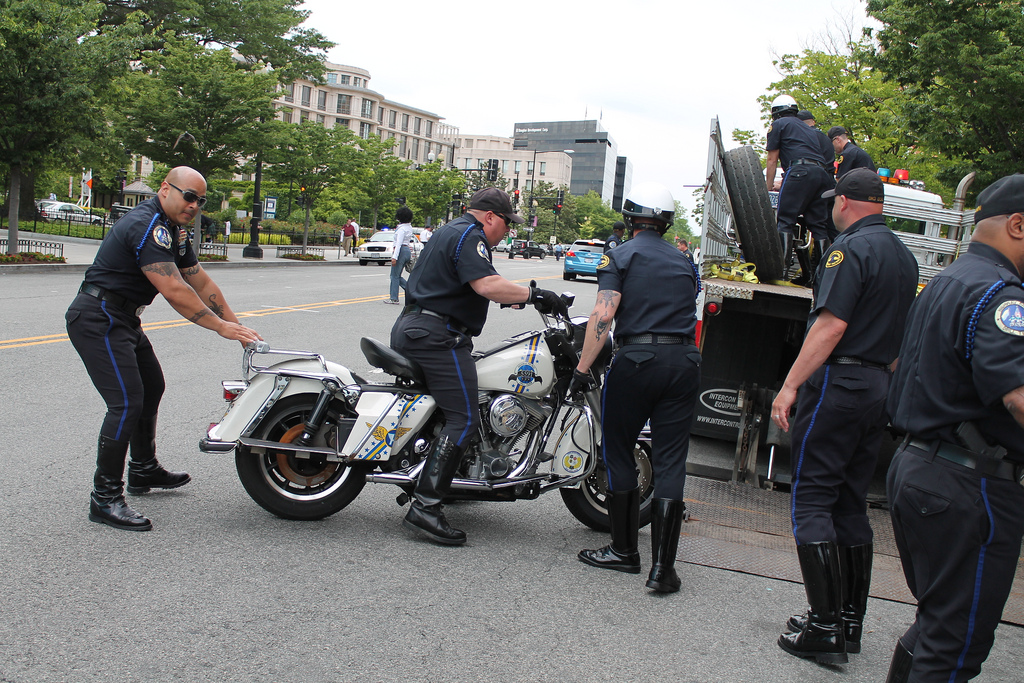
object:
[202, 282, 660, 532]
bike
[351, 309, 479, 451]
torso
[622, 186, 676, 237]
head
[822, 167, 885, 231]
head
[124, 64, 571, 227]
wall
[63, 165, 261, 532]
man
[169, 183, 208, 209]
sunglasses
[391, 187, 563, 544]
man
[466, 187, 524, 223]
hat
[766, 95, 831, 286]
man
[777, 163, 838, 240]
pants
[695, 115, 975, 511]
truck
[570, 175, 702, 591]
man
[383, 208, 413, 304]
woman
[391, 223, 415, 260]
shirt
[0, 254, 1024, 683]
ground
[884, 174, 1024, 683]
man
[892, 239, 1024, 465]
shirt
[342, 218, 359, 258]
person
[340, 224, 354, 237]
shirt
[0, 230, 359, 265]
sidewalk